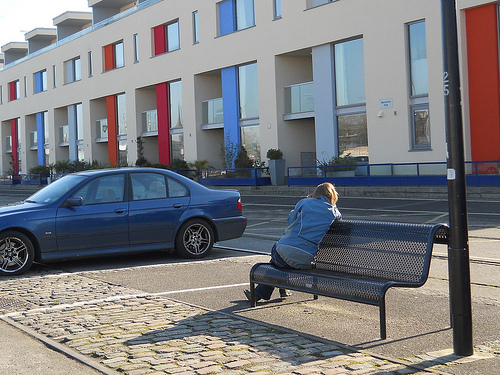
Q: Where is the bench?
A: On the side of the sidewalk.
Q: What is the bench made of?
A: Metal.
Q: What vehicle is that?
A: Car.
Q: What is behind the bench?
A: Road.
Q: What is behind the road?
A: Building.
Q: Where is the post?
A: Beside the bench.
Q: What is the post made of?
A: Metal.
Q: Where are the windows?
A: On the building.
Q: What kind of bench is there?
A: Metal.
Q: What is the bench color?
A: Black.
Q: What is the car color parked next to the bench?
A: Blue.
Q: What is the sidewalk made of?
A: Concrete.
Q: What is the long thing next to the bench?
A: Pole.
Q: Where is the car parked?
A: In a parking space.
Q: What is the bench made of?
A: Metal.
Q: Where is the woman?
A: Sitting on the bench.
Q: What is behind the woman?
A: Metal pole.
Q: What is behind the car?
A: Building.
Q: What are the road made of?
A: Cement.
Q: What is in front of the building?
A: Bushes.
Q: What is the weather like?
A: Sunny.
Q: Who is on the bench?
A: Person.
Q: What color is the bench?
A: Black.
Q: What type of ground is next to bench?
A: Stone.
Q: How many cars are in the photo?
A: One.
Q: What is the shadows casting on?
A: Ground.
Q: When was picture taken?
A: Daytime.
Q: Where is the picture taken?
A: On a bench.